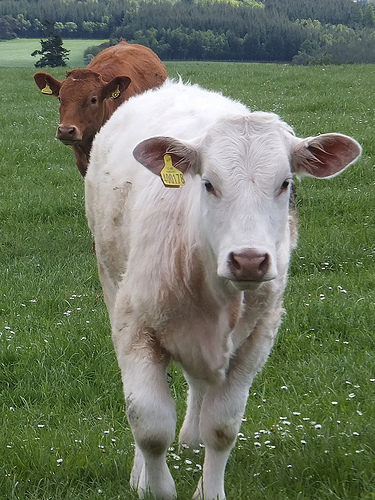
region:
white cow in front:
[76, 82, 351, 480]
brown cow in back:
[23, 33, 177, 159]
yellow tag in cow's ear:
[159, 151, 186, 189]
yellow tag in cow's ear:
[32, 71, 54, 103]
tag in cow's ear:
[107, 83, 124, 101]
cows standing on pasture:
[24, 40, 326, 498]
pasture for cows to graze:
[15, 36, 354, 483]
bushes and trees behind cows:
[92, 2, 371, 65]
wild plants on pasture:
[263, 413, 364, 466]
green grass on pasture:
[34, 478, 79, 496]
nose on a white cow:
[229, 249, 271, 283]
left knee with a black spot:
[200, 418, 244, 452]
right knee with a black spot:
[135, 429, 176, 453]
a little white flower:
[279, 383, 289, 391]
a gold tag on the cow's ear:
[158, 151, 186, 189]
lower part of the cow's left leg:
[191, 450, 236, 499]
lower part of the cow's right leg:
[139, 457, 178, 498]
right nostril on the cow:
[257, 258, 269, 271]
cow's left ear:
[285, 128, 365, 177]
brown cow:
[31, 46, 166, 175]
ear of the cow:
[297, 113, 361, 189]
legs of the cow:
[92, 378, 268, 476]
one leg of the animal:
[128, 371, 184, 485]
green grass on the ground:
[21, 401, 114, 457]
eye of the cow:
[190, 149, 241, 206]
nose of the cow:
[222, 229, 287, 284]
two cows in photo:
[21, 8, 364, 262]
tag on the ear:
[142, 145, 198, 206]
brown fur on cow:
[93, 40, 147, 78]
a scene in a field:
[1, 5, 370, 498]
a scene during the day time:
[5, 1, 369, 494]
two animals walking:
[19, 31, 372, 498]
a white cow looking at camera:
[68, 62, 365, 498]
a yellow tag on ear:
[150, 135, 191, 208]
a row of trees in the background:
[2, 0, 373, 87]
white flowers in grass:
[6, 93, 373, 495]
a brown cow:
[26, 31, 181, 203]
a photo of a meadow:
[5, 8, 369, 498]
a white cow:
[85, 76, 360, 498]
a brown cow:
[30, 40, 169, 173]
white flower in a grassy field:
[0, 61, 373, 498]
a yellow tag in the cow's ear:
[131, 133, 196, 186]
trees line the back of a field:
[4, 3, 373, 64]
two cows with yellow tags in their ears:
[32, 36, 359, 497]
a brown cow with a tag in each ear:
[34, 35, 166, 174]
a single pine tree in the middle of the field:
[27, 29, 72, 66]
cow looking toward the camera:
[83, 71, 362, 495]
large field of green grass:
[3, 38, 371, 497]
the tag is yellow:
[160, 153, 184, 184]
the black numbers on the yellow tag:
[161, 152, 185, 186]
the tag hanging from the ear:
[132, 136, 195, 188]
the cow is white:
[85, 70, 363, 498]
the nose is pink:
[229, 250, 269, 281]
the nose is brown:
[57, 128, 74, 138]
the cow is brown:
[33, 37, 167, 253]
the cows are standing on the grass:
[0, 0, 374, 499]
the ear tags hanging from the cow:
[34, 37, 167, 252]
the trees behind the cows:
[0, 1, 373, 499]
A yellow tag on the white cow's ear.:
[157, 152, 190, 188]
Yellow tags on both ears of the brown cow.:
[37, 80, 130, 101]